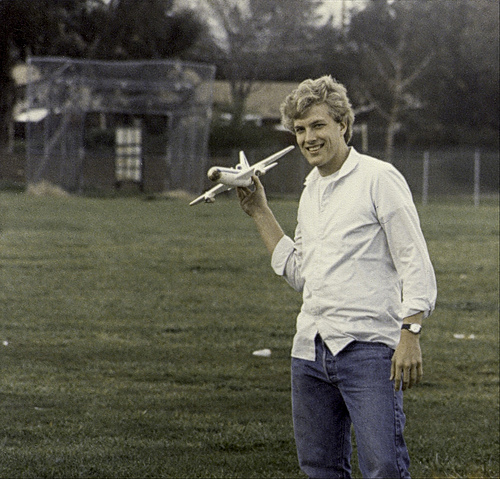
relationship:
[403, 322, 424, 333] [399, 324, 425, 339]
watch on wrist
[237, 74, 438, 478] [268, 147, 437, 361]
man has shirt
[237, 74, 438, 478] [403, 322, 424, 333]
man has watch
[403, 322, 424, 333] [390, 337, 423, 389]
watch on hand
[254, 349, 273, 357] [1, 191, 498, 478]
trash on grass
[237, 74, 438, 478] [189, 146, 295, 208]
man holding airplane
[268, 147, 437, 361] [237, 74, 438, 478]
shirt on man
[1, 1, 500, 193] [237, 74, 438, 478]
trees behind man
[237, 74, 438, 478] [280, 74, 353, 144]
man has hair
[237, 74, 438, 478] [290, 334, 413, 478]
man wearing pants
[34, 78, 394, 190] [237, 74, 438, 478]
building behind man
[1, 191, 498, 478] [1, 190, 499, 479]
grass covers ground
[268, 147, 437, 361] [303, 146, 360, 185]
shirt has collar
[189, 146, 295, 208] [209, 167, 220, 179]
airplane has tip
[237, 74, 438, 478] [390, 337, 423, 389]
man has hand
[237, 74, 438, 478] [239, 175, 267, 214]
man has right hand